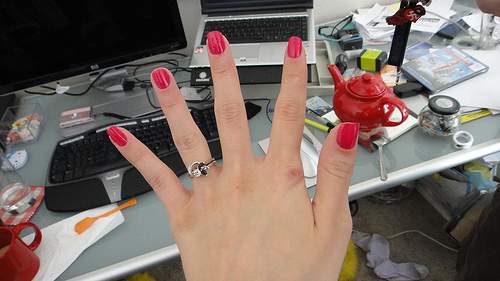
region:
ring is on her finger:
[169, 154, 225, 184]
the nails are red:
[190, 36, 311, 58]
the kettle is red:
[315, 66, 409, 133]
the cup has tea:
[5, 223, 51, 276]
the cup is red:
[5, 223, 45, 275]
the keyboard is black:
[40, 109, 248, 211]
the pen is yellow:
[303, 114, 328, 139]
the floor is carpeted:
[382, 210, 441, 266]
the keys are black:
[207, 17, 303, 44]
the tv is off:
[5, 3, 186, 70]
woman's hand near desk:
[31, 8, 472, 274]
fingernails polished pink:
[96, 23, 405, 171]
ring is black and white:
[182, 150, 227, 190]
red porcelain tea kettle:
[328, 59, 412, 143]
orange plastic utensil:
[70, 196, 148, 244]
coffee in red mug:
[0, 220, 56, 279]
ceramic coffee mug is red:
[5, 220, 56, 277]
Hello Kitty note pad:
[5, 148, 34, 172]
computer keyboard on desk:
[45, 95, 283, 207]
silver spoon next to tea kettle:
[368, 128, 395, 188]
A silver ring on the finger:
[176, 148, 219, 180]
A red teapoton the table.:
[341, 67, 400, 137]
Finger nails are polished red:
[139, 56, 363, 145]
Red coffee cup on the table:
[7, 226, 49, 269]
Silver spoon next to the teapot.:
[367, 135, 391, 185]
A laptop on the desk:
[183, 10, 322, 82]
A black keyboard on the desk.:
[28, 122, 227, 188]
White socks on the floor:
[365, 233, 405, 268]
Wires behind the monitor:
[46, 65, 189, 90]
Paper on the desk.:
[429, 38, 494, 110]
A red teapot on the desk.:
[323, 66, 413, 148]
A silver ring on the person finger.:
[171, 147, 228, 188]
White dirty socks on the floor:
[361, 220, 412, 280]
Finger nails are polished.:
[193, 35, 308, 57]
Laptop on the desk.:
[174, 12, 326, 88]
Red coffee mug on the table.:
[5, 220, 39, 267]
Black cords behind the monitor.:
[29, 73, 181, 94]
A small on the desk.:
[371, 119, 391, 191]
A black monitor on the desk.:
[13, 15, 188, 81]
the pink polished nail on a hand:
[107, 123, 129, 146]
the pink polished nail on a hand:
[152, 67, 172, 91]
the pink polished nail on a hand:
[207, 32, 224, 54]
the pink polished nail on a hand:
[286, 35, 298, 54]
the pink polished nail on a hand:
[333, 123, 358, 145]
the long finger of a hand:
[111, 125, 182, 208]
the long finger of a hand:
[151, 65, 210, 174]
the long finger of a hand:
[208, 30, 250, 155]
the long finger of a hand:
[272, 38, 310, 158]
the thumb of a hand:
[315, 122, 357, 225]